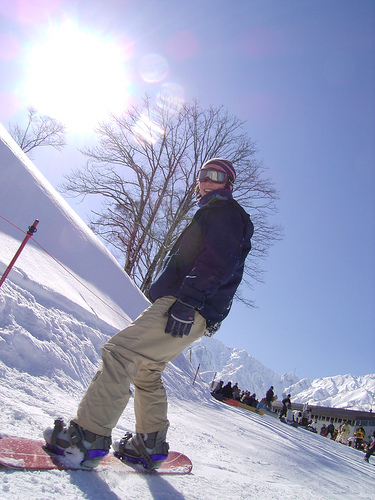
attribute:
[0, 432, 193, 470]
snowboard — red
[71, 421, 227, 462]
boots — snowboarding boots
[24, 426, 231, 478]
snowboard — red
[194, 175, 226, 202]
mouth — open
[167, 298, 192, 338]
blue gloves — dark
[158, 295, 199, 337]
gloves — blue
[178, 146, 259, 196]
hat — multicolored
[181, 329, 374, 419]
mountains — snowy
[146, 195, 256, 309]
jacket — blue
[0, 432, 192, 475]
snow board — red 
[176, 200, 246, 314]
jacket — blue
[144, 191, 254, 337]
coat — blue, winter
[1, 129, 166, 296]
snowboard — red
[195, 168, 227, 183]
eyewear — protective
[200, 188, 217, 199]
smile — open-mouthed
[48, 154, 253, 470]
individual — smiling